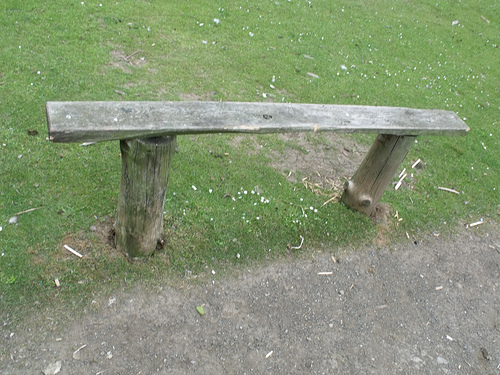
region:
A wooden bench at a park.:
[43, 100, 470, 258]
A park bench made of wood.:
[43, 101, 470, 261]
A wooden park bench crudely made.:
[44, 102, 468, 257]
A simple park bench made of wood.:
[45, 101, 470, 258]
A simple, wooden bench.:
[46, 101, 471, 258]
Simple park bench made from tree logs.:
[45, 99, 470, 261]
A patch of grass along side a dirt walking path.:
[1, 0, 499, 340]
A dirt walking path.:
[1, 212, 498, 374]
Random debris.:
[63, 244, 83, 258]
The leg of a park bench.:
[112, 135, 172, 256]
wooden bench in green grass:
[34, 86, 471, 258]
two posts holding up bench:
[112, 140, 422, 262]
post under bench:
[115, 139, 190, 266]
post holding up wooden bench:
[332, 131, 413, 223]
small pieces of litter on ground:
[1, 4, 496, 281]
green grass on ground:
[0, 7, 499, 287]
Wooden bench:
[42, 95, 472, 263]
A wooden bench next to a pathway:
[42, 98, 470, 373]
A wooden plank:
[46, 98, 471, 148]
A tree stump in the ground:
[112, 132, 178, 258]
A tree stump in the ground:
[335, 131, 418, 218]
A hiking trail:
[0, 204, 499, 372]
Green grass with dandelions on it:
[1, 0, 498, 100]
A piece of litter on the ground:
[62, 241, 84, 259]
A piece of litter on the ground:
[437, 185, 459, 196]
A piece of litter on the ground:
[468, 218, 483, 228]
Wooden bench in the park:
[33, 49, 495, 284]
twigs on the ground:
[273, 205, 314, 271]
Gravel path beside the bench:
[351, 265, 450, 374]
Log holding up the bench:
[119, 130, 192, 273]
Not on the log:
[342, 172, 396, 229]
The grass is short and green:
[205, 140, 262, 217]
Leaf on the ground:
[177, 286, 221, 326]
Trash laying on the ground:
[205, 16, 462, 141]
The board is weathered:
[153, 56, 397, 136]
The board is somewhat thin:
[424, 98, 486, 156]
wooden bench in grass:
[42, 102, 468, 259]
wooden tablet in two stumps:
[48, 101, 467, 135]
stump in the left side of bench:
[119, 131, 177, 254]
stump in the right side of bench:
[340, 127, 425, 214]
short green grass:
[8, 73, 497, 305]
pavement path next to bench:
[3, 214, 495, 374]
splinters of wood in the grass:
[39, 147, 489, 262]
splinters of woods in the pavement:
[311, 219, 482, 291]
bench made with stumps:
[46, 102, 465, 264]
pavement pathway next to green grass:
[0, 221, 496, 373]